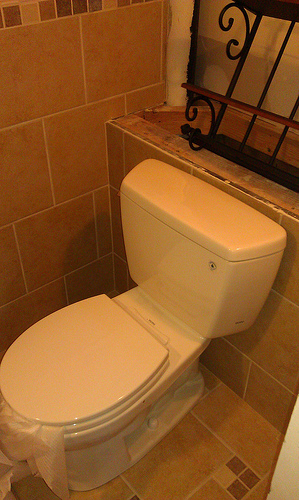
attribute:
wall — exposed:
[156, 4, 293, 185]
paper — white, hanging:
[0, 414, 90, 478]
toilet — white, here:
[46, 222, 198, 442]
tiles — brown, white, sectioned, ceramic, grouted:
[178, 410, 279, 493]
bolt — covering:
[146, 404, 192, 441]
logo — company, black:
[189, 244, 235, 281]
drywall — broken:
[98, 98, 185, 168]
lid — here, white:
[75, 302, 185, 407]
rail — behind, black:
[203, 67, 262, 142]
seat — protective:
[52, 258, 214, 436]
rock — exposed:
[207, 162, 271, 198]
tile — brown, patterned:
[23, 5, 99, 37]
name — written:
[180, 241, 259, 298]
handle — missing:
[244, 266, 284, 291]